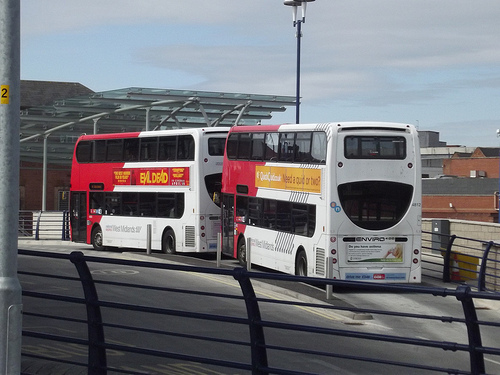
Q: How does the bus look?
A: Red and white.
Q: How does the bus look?
A: Double decker.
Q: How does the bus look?
A: Double decker.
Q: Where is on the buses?
A: The roadway.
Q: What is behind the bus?
A: Metal railing.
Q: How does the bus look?
A: Red and White.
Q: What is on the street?
A: Two Buses.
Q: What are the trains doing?
A: Parked.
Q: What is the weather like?
A: Sunny.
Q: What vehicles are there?
A: Bus.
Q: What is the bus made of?
A: Metal.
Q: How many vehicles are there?
A: Two.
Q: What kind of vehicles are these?
A: Double-decker buses.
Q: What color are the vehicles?
A: Red, white, and yellow.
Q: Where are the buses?
A: Between the railings.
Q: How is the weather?
A: Partly cloudy.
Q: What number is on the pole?
A: 2.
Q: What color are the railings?
A: Black.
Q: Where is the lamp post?
A: Behind the bus.